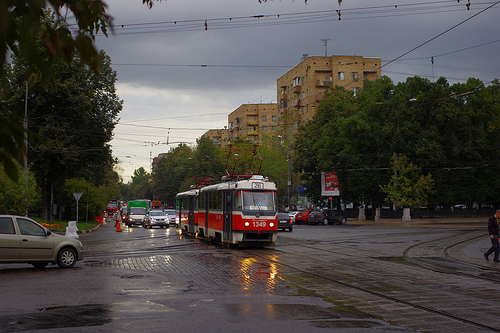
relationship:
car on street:
[7, 214, 77, 265] [175, 271, 240, 310]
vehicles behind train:
[131, 191, 179, 235] [163, 184, 271, 241]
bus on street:
[175, 175, 278, 249] [110, 221, 442, 321]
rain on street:
[142, 255, 418, 313] [57, 241, 451, 326]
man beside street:
[481, 210, 499, 264] [437, 234, 498, 274]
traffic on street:
[121, 168, 295, 251] [93, 226, 349, 306]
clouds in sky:
[124, 14, 251, 92] [101, 4, 493, 87]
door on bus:
[219, 186, 231, 236] [175, 175, 278, 249]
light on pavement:
[232, 246, 284, 296] [4, 271, 460, 331]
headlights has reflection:
[244, 222, 249, 227] [233, 254, 282, 294]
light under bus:
[188, 226, 202, 240] [172, 170, 286, 255]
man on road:
[483, 210, 499, 263] [417, 241, 498, 302]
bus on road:
[168, 168, 284, 251] [132, 237, 381, 317]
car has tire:
[2, 206, 89, 278] [53, 241, 80, 268]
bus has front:
[175, 175, 278, 249] [235, 170, 284, 246]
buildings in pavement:
[133, 52, 498, 175] [4, 271, 460, 331]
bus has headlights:
[175, 175, 278, 249] [241, 215, 275, 231]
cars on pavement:
[121, 192, 179, 230] [4, 271, 460, 331]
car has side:
[2, 206, 89, 278] [1, 221, 73, 257]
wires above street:
[106, 4, 496, 87] [92, 230, 428, 311]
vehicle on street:
[166, 166, 291, 255] [139, 230, 368, 295]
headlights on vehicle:
[241, 215, 279, 231] [172, 177, 286, 251]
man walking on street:
[483, 210, 499, 263] [3, 218, 498, 328]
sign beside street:
[71, 187, 84, 218] [3, 218, 498, 328]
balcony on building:
[291, 85, 303, 94] [277, 57, 381, 142]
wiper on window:
[250, 188, 262, 211] [242, 187, 276, 216]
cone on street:
[115, 219, 125, 233] [3, 218, 498, 328]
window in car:
[18, 217, 45, 235] [0, 212, 85, 268]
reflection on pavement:
[236, 255, 286, 318] [4, 219, 498, 331]